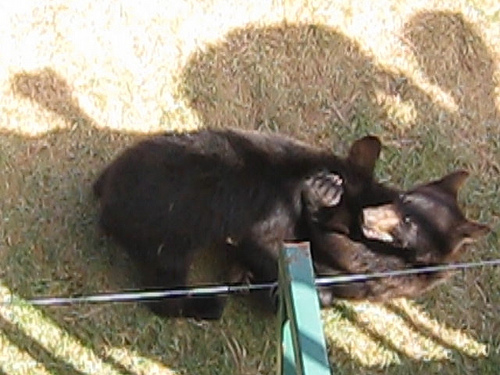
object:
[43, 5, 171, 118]
sunlight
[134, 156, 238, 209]
fur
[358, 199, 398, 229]
snout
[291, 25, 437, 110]
hay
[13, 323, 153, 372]
grass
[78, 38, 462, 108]
earth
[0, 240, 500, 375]
fence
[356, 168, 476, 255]
head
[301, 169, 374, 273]
arms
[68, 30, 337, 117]
air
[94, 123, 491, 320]
bear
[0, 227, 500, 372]
enclosure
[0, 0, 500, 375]
zoo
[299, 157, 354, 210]
claws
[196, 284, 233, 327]
paw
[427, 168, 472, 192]
ear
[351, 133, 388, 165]
ear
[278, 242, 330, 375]
pole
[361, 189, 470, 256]
face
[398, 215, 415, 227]
eye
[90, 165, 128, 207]
tail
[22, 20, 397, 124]
ground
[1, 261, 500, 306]
cable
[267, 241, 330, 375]
brace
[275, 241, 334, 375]
structure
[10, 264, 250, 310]
deck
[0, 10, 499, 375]
shadow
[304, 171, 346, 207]
paw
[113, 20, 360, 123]
grass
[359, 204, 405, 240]
muzzle